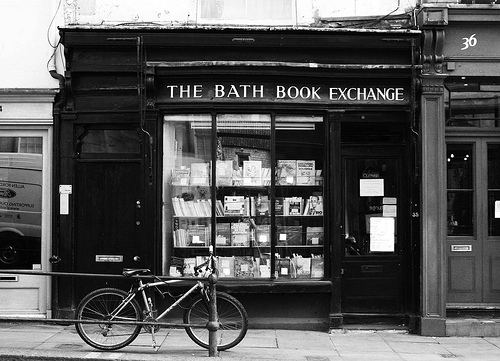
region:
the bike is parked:
[54, 250, 239, 356]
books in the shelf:
[157, 120, 351, 311]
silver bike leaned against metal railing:
[76, 261, 248, 353]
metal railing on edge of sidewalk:
[15, 268, 222, 355]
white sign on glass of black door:
[367, 215, 395, 253]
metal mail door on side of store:
[447, 242, 475, 253]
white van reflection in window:
[0, 151, 45, 263]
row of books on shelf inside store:
[276, 159, 321, 187]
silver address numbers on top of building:
[457, 31, 482, 53]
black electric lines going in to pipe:
[45, 2, 65, 80]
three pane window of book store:
[158, 108, 329, 285]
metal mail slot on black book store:
[93, 253, 124, 262]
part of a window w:
[289, 225, 301, 239]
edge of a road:
[305, 328, 316, 358]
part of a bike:
[233, 295, 239, 308]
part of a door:
[358, 263, 367, 277]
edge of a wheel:
[126, 298, 134, 303]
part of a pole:
[213, 323, 223, 334]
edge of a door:
[408, 269, 429, 307]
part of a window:
[15, 215, 31, 246]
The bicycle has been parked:
[71, 241, 250, 353]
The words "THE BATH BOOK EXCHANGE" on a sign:
[160, 74, 410, 111]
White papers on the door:
[353, 167, 404, 255]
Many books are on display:
[164, 156, 328, 279]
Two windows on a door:
[440, 134, 499, 242]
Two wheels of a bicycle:
[71, 287, 251, 353]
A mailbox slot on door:
[446, 237, 476, 257]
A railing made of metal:
[1, 263, 222, 356]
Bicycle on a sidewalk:
[1, 314, 499, 358]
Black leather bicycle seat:
[119, 260, 154, 282]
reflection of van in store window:
[2, 135, 49, 276]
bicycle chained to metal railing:
[25, 251, 270, 352]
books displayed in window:
[164, 121, 320, 278]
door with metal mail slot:
[445, 123, 497, 315]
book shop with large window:
[52, 73, 419, 328]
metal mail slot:
[92, 253, 127, 266]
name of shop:
[164, 81, 411, 103]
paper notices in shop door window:
[357, 173, 404, 253]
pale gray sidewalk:
[251, 330, 483, 357]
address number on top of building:
[441, 15, 498, 63]